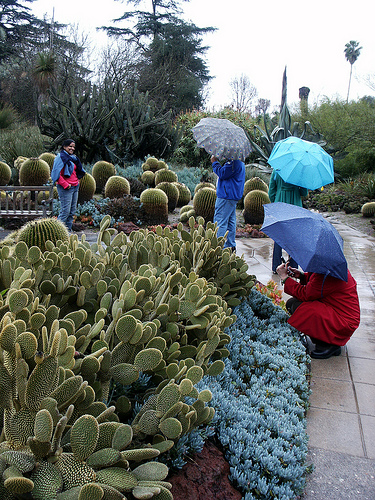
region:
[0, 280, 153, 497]
many paddle shaped cacti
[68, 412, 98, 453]
spiny green cactus paddle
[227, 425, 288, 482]
small blue cactus plants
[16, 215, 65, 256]
large green barrel cactus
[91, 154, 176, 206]
groups of barrel cacti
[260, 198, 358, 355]
person with umbrella looking closely at cactus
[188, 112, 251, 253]
person with peacock print umbrella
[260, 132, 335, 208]
person with teal umbrella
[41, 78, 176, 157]
large cactus cluster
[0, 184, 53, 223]
bench among the cacti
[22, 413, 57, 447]
green cactus at plant farm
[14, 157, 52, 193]
green cactus at plant farm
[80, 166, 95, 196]
green cactus at plant farm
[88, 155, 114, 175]
green cactus at plant farm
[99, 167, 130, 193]
green cactus at plant farm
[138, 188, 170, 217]
green cactus at plant farm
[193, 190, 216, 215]
green cactus at plant farm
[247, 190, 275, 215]
green cactus at plant farm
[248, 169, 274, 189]
green cactus at plant farm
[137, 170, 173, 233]
Small grene cactus in a garden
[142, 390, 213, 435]
Small grene cactus in a garden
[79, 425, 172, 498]
Small grene cactus in a garden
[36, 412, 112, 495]
Small grene cactus in a garden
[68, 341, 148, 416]
Small grene cactus in a garden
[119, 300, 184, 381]
Small grene cactus in a garden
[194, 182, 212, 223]
Small grene cactus in a garden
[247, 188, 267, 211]
Small grene cactus in a garden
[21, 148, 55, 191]
Small grene cactus in a garden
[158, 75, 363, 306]
three open umbrellas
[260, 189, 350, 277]
one dark blue umbrella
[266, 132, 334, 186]
one light blue umbrella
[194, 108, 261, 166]
one gray umbrella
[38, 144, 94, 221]
red shirt with two shirts on shoulder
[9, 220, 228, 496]
lots of green cactus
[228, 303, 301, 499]
blue flowers on the bottom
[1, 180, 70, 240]
an empty bench behind woman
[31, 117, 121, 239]
a woman with no umbrella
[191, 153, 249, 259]
blue jacket and blue pants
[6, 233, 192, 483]
bunch of cactus plants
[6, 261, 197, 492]
bunch of short cactus plants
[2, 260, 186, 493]
bunch of short cacti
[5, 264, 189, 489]
bunch of round cacti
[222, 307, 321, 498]
bunch of green succulents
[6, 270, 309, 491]
cactus and succulent plants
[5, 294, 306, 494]
cactus and succulent garden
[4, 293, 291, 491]
cacti and succulent garden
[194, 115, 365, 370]
people in garden with umbrellas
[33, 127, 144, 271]
woman posing for photo in garden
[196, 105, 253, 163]
a large open umbrella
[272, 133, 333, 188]
a large open umbrella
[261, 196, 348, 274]
a large open umbrella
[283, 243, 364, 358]
a person is sitting down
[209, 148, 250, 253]
a person is standing up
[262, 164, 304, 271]
a person is standing up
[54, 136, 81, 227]
a person is standing up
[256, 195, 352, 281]
a blue umbrella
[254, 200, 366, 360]
a person with blue umbrella wearing red coat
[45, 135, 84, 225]
a woman wearing a red shirt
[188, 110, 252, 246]
man wearing a blue jacket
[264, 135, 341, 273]
a woman with a green umbrella